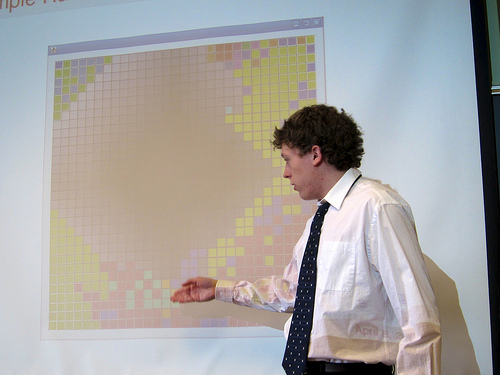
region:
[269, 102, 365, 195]
a man with brown hair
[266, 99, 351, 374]
man with brown hair can be seen wearing a neck tie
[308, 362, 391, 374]
a black belt can be seen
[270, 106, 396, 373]
the man with brown hair is wearing a black belt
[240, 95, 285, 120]
yellow squares can be seen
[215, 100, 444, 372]
the man with brown hair is wearing a white shirt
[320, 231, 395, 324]
a pocket can be seen on the white shirt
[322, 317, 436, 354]
words and numbers that are projected can be seen on the man's shirt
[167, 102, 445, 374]
the man with brown hair is using his right hand to point to the screen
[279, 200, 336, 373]
necktie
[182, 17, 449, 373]
a dorky looking teacher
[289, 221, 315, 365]
a tie the man is wearing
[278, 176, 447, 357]
the shirt the man is wearing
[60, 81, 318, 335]
the man pointing to a weird screen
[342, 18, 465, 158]
a white board the man is next to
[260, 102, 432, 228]
the face of what seems to be a professor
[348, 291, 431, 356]
the date the picture was taken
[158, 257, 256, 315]
the man's hand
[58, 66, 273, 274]
a graph with many different colors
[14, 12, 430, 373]
what appears to be a lesson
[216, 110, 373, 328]
man in white dress shirt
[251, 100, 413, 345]
man with black tie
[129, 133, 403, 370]
man with brown hair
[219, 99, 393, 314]
man in front of yellow picture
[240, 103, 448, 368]
man in front of white wall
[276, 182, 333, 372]
tie with white dots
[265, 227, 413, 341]
white shirt with one pocket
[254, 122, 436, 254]
man not smiling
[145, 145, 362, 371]
man extends right hand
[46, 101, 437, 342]
different colored squares on picture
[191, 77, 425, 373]
man with messy hair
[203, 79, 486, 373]
man in a shirt too big for him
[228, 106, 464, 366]
man with a black tie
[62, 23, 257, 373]
man giving a presentation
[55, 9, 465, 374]
man pointing at the graph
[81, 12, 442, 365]
pixels in orange and yellow shades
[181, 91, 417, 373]
a Caucasian man presenting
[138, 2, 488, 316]
a teen giving a presentation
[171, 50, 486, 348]
a man in a white shirt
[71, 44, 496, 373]
a man with hand stretched out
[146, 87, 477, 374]
man in a tie giving a presentation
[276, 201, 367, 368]
navy tie with white polka dots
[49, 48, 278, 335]
picture with many squares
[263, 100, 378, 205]
man's head with curly brown hair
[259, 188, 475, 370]
white dress shirt with wrinkles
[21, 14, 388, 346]
white projection screen with a presentation on it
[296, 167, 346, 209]
young man with acne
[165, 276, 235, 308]
hand presenting a report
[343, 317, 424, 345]
date projected on a white shirt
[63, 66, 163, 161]
square mosaic with pink yellow and grey